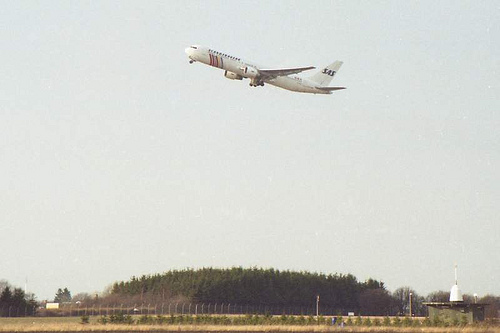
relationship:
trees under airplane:
[0, 264, 499, 319] [179, 43, 342, 103]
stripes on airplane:
[210, 52, 223, 67] [175, 17, 381, 109]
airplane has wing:
[185, 44, 348, 95] [268, 54, 311, 86]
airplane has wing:
[182, 40, 347, 102] [313, 82, 347, 94]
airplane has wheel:
[182, 40, 347, 102] [186, 57, 196, 64]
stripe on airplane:
[209, 53, 223, 69] [185, 38, 345, 94]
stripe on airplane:
[210, 50, 222, 67] [182, 40, 347, 102]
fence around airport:
[59, 267, 442, 327] [103, 291, 397, 304]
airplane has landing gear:
[185, 44, 348, 95] [254, 77, 267, 88]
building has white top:
[422, 264, 490, 329] [448, 262, 465, 302]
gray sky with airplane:
[73, 105, 464, 240] [185, 44, 348, 95]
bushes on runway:
[78, 314, 470, 329] [0, 310, 498, 328]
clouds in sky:
[0, 0, 498, 300] [2, 0, 498, 302]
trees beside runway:
[95, 264, 394, 315] [0, 310, 498, 328]